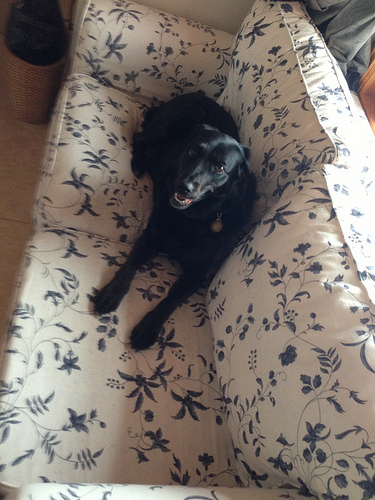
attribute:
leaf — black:
[312, 373, 322, 388]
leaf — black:
[297, 373, 312, 385]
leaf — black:
[300, 385, 313, 394]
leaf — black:
[325, 394, 345, 412]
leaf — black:
[346, 387, 367, 405]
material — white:
[202, 162, 373, 498]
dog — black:
[91, 89, 266, 354]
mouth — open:
[167, 180, 209, 228]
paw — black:
[128, 316, 160, 350]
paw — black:
[90, 288, 121, 314]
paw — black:
[130, 155, 147, 177]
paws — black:
[130, 310, 165, 348]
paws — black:
[95, 279, 124, 312]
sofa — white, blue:
[66, 32, 156, 351]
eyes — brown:
[189, 141, 234, 174]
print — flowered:
[241, 61, 287, 130]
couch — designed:
[63, 5, 373, 473]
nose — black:
[178, 180, 193, 191]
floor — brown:
[1, 105, 49, 348]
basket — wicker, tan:
[6, 57, 53, 123]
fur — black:
[102, 95, 259, 341]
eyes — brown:
[179, 139, 225, 176]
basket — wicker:
[0, 3, 70, 127]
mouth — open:
[170, 184, 200, 205]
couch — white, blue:
[3, 2, 372, 498]